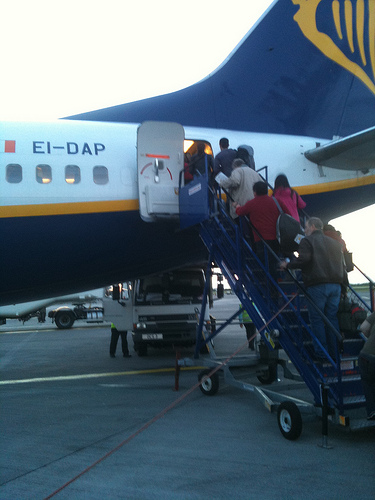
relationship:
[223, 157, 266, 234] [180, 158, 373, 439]
passenger on stairs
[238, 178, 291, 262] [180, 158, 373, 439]
person on stairs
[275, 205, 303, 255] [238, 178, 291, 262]
bag with person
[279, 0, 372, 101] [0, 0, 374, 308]
logo on plane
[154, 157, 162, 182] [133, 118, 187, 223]
handle on door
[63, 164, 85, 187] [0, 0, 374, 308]
window on plane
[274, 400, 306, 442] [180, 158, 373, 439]
wheel on stairs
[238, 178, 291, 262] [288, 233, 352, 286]
person has a jacket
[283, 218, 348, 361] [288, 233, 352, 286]
man wearing a jacket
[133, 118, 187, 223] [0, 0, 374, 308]
door on plane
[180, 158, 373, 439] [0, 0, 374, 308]
stairs by plane